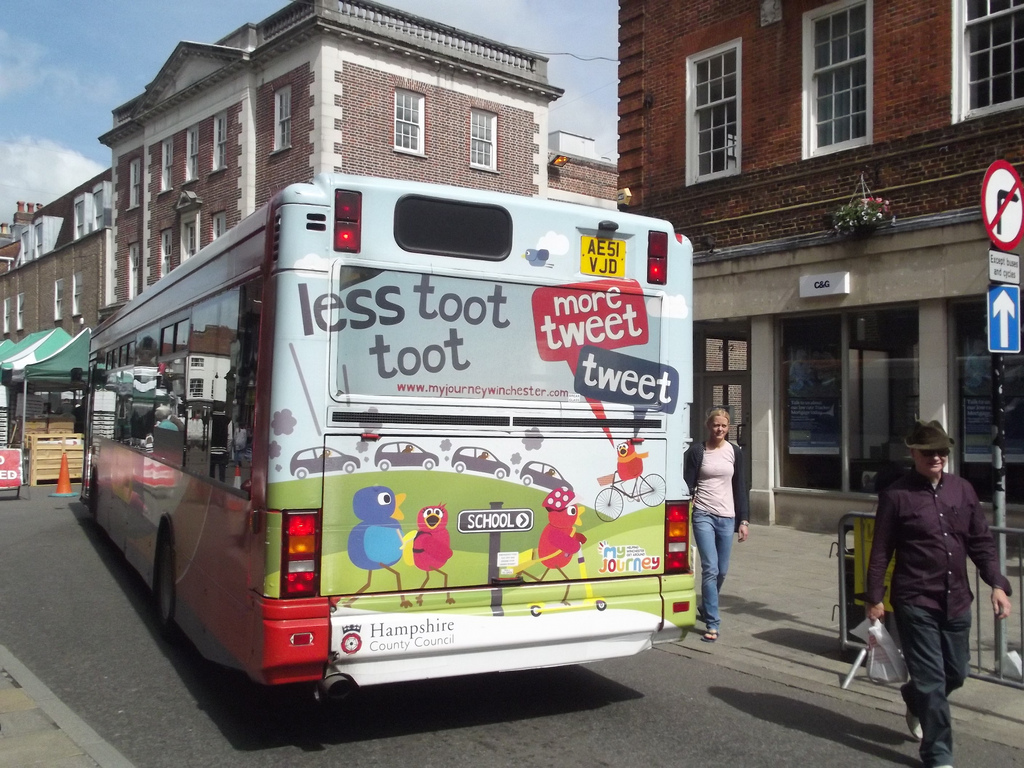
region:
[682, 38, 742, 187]
window on brick building facing passenger bus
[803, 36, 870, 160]
window on brick building facing passenger bus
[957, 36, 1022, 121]
window on brick building facing passenger bus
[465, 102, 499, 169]
window on brick building facing passenger bus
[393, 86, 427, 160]
window on brick building facing passenger bus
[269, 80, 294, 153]
window on brick building facing passenger bus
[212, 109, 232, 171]
window on brick building facing passenger bus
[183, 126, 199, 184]
window on brick building facing passenger bus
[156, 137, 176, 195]
window on brick building facing passenger bus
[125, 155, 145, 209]
window on brick building facing passenger bus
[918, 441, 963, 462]
a man wearing sunglasses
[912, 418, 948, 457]
a man wearing a hat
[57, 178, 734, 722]
a bus with paintings on it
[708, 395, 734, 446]
a girl with blonde hair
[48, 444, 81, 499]
a orange traffic cone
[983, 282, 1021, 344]
a blue and white sign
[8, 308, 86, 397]
a green and white canopy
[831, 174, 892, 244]
a flower pot with flowers hanging on a building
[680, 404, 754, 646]
Woman wearing blue jeans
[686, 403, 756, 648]
Woman in blue jeans wearing black jacket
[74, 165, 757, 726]
Woman and bus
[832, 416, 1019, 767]
Man in long sleeves walking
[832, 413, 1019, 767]
Man in long sleeves wearing hat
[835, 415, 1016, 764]
Man in black pants carrying plastic bag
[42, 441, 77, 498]
An orange cone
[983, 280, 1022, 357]
White arrow on blue rectangular sign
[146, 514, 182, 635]
back black tire on bus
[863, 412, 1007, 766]
man wearing brown hat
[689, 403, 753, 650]
woman wearing blue jacket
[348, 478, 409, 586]
blue bird painted on bus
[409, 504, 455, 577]
red bird painted on bus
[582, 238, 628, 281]
yellow sign with black letters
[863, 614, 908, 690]
small white plastic bag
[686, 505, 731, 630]
light blue jeans on woman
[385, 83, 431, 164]
A window on a building.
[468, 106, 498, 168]
A window on a building.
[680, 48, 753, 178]
A window on a building.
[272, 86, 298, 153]
A window on a building.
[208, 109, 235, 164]
A window on a building.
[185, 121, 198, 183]
A window on a building.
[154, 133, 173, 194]
A window on a building.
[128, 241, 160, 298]
A window on a building.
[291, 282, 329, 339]
black letter on bus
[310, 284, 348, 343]
black letter on bus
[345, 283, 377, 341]
black letter on bus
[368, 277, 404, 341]
black letter on bus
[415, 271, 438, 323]
black letter on bus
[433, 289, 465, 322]
black letter on bus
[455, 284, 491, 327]
black letter on bus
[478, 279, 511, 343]
black letter on bus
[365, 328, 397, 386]
black letter on bus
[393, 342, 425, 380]
black letter on bus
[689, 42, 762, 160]
A window on a building.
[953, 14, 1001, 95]
A window on a building.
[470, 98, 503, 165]
A window on a building.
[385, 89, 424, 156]
A window on a building.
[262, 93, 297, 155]
A window on a building.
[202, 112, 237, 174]
A window on a building.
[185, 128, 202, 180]
A window on a building.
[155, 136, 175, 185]
A window on a building.